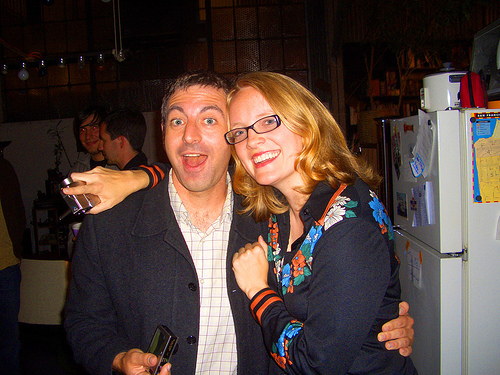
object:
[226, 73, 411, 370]
woman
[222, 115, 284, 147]
glasses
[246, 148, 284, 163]
maxillary dentition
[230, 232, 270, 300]
hand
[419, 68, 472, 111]
crock pot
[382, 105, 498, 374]
fridge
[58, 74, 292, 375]
man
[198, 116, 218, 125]
left eye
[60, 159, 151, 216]
hand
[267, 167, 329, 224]
neck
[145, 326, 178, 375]
camera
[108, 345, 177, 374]
hand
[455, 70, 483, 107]
bag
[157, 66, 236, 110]
hair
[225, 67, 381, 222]
hair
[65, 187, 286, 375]
jacket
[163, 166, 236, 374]
shirt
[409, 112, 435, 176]
papers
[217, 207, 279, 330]
man's chest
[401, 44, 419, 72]
books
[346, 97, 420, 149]
shelf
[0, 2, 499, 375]
background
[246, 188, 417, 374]
shirt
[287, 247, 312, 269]
flowers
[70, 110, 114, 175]
person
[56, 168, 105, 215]
camera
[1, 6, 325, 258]
wall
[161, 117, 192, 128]
eye brows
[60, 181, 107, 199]
pointer finger